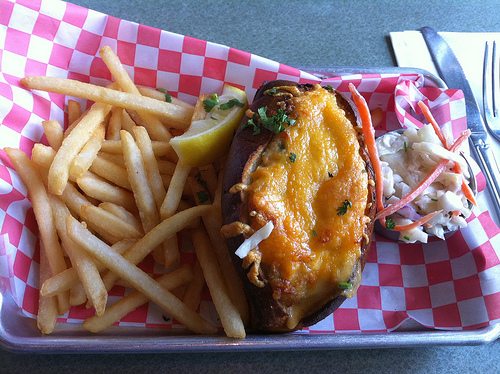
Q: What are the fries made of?
A: Potato.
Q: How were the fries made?
A: Fried.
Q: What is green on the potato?
A: Herbs.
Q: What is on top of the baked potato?
A: Cheese.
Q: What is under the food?
A: Checkered paper.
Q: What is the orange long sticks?
A: Carrots.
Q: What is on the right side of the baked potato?
A: Coleslaw.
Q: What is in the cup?
A: Coleslaw.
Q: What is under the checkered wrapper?
A: Gray tray.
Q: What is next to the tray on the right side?
A: Knife.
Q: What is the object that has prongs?
A: Fork.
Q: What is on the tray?
A: Food.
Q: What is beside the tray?
A: Knife and fork.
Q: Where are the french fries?
A: Beside the baked potato.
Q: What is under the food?
A: Wax paper.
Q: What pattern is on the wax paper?
A: Checker.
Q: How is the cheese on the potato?
A: Melted.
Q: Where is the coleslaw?
A: Beside the potato.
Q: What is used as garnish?
A: A lemon.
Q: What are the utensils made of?
A: Metal.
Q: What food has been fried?
A: French fries.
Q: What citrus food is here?
A: Lemon wedge.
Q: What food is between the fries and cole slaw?
A: Baked potato.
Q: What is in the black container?
A: Cole slaw.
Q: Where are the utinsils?
A: On the napkin.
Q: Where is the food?
A: On a grey tray.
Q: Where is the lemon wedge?
A: On the fries.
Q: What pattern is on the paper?
A: Red and white checks.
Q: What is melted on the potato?
A: Cheese.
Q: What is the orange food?
A: Carrots.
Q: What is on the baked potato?
A: Cheese and green onion.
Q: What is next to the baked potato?
A: French fries and cole slaw.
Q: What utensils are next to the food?
A: A knife and fork.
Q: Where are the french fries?
A: On the plate.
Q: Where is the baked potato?
A: On a plate.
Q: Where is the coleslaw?
A: On a plate.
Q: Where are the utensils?
A: On a napkin next to plate.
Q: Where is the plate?
A: On a table.